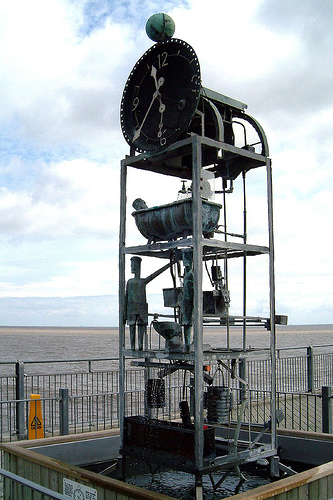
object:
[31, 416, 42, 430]
sign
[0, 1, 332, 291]
clouds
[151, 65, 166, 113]
hand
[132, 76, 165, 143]
hand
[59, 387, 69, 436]
object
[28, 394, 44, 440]
yellow sign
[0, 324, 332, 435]
water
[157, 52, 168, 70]
twelve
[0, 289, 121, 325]
hill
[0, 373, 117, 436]
fencing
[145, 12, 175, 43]
globe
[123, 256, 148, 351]
humanoid figure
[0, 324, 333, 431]
ripple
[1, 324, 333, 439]
ocean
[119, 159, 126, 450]
metal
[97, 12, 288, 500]
art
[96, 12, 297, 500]
tower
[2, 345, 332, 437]
fence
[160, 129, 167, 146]
numbers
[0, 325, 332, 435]
sea water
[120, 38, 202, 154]
clock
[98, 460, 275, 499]
water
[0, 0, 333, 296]
sky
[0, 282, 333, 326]
background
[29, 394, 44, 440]
item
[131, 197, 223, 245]
bath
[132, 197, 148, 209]
man